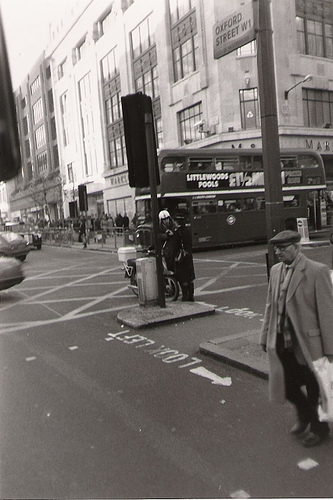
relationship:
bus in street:
[133, 147, 329, 254] [0, 239, 332, 497]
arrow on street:
[189, 366, 232, 387] [0, 239, 332, 497]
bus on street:
[134, 147, 327, 250] [0, 239, 332, 497]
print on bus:
[183, 172, 229, 188] [145, 138, 328, 233]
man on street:
[259, 229, 333, 447] [5, 297, 332, 497]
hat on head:
[269, 230, 302, 245] [268, 238, 298, 265]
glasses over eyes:
[271, 244, 291, 249] [273, 245, 284, 249]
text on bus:
[196, 180, 216, 188] [133, 147, 329, 254]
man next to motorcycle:
[150, 205, 180, 245] [111, 242, 178, 303]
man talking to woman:
[150, 205, 180, 245] [166, 215, 197, 299]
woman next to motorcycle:
[166, 215, 197, 299] [111, 242, 178, 303]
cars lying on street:
[0, 231, 30, 266] [26, 248, 204, 349]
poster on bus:
[186, 168, 303, 189] [134, 147, 327, 250]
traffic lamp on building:
[288, 67, 318, 106] [272, 3, 330, 141]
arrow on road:
[187, 360, 238, 407] [73, 269, 244, 472]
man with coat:
[259, 229, 333, 447] [266, 250, 331, 410]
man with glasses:
[259, 229, 333, 447] [271, 242, 299, 252]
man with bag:
[259, 229, 333, 447] [309, 353, 331, 425]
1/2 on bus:
[239, 170, 255, 189] [142, 142, 328, 252]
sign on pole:
[211, 1, 252, 60] [254, 0, 286, 280]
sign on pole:
[212, 1, 256, 60] [251, 1, 289, 237]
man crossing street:
[259, 229, 333, 447] [1, 323, 332, 495]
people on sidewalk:
[26, 211, 129, 241] [26, 228, 136, 250]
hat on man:
[267, 230, 302, 244] [259, 229, 333, 447]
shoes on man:
[288, 417, 326, 446] [259, 229, 333, 447]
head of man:
[263, 226, 307, 266] [244, 228, 318, 386]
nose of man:
[275, 247, 280, 254] [259, 229, 333, 447]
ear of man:
[289, 240, 304, 256] [243, 199, 331, 365]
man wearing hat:
[259, 229, 333, 447] [269, 228, 300, 243]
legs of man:
[279, 367, 331, 437] [257, 228, 332, 448]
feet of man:
[289, 412, 330, 445] [259, 229, 333, 447]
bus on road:
[133, 147, 329, 254] [2, 231, 329, 498]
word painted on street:
[107, 328, 155, 350] [1, 208, 326, 498]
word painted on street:
[144, 343, 202, 368] [1, 208, 326, 498]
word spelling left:
[107, 328, 155, 350] [105, 327, 154, 348]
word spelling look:
[144, 343, 202, 368] [142, 342, 202, 369]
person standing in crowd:
[114, 211, 124, 235] [26, 209, 133, 244]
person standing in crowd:
[99, 212, 108, 237] [26, 209, 133, 244]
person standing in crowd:
[121, 210, 129, 231] [26, 209, 133, 244]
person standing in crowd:
[92, 213, 100, 243] [26, 209, 133, 244]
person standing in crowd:
[100, 214, 110, 243] [26, 209, 133, 244]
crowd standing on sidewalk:
[26, 209, 133, 244] [52, 226, 124, 242]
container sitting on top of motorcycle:
[117, 246, 138, 262] [118, 242, 177, 300]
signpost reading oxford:
[207, 2, 265, 67] [214, 11, 241, 35]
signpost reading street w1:
[207, 2, 265, 67] [214, 18, 252, 44]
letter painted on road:
[105, 329, 203, 369] [2, 231, 329, 498]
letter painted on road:
[143, 342, 170, 354] [2, 231, 329, 498]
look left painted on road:
[105, 328, 201, 369] [2, 231, 329, 498]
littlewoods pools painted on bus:
[186, 171, 229, 188] [133, 147, 329, 254]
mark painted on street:
[104, 330, 155, 349] [0, 239, 332, 497]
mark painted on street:
[115, 329, 139, 340] [0, 239, 332, 497]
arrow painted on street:
[189, 366, 232, 387] [0, 239, 332, 497]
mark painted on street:
[161, 348, 187, 363] [0, 239, 332, 497]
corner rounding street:
[100, 247, 150, 261] [0, 239, 332, 497]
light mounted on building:
[284, 73, 313, 105] [43, 1, 322, 228]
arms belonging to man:
[310, 255, 332, 356] [258, 228, 322, 447]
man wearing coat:
[242, 225, 330, 455] [257, 253, 322, 404]